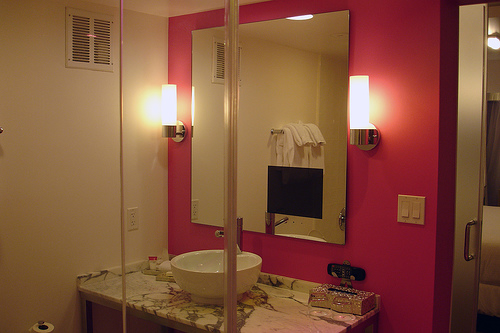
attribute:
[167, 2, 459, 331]
wall — pink, orange, red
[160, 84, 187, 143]
light — on, cylinder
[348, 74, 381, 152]
light — on, cylinder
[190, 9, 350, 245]
mirror — large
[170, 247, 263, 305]
sink — bowl, white, porcelain, round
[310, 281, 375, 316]
kleenex — empty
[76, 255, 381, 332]
counter — granite, marble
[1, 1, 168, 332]
wall — white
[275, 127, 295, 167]
towel — white, reflection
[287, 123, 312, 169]
towel — white, reflection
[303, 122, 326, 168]
towel — white, reflection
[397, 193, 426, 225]
light switch — double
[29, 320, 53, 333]
toilet paper — half used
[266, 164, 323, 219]
television screen — inset, black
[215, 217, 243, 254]
faucet — tall, metal